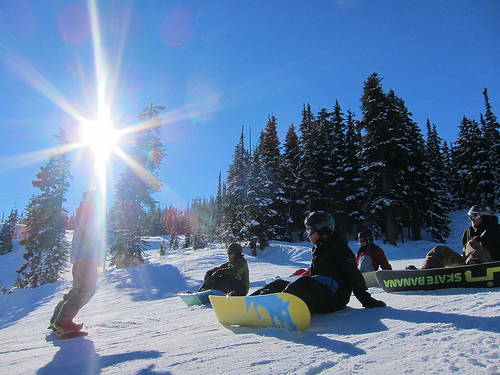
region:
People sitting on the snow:
[172, 207, 495, 332]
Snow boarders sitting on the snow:
[172, 198, 498, 333]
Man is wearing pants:
[245, 276, 347, 317]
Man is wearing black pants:
[247, 275, 350, 310]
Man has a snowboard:
[205, 288, 314, 331]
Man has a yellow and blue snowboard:
[205, 287, 314, 334]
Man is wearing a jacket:
[307, 232, 370, 302]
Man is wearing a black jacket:
[307, 236, 370, 294]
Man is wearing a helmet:
[305, 207, 335, 235]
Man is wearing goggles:
[300, 216, 337, 231]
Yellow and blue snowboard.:
[208, 293, 310, 333]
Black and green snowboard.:
[371, 261, 498, 293]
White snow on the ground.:
[3, 215, 497, 372]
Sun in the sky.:
[72, 105, 129, 165]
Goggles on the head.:
[300, 207, 335, 246]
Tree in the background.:
[112, 99, 165, 265]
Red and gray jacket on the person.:
[353, 225, 391, 277]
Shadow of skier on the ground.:
[35, 330, 173, 372]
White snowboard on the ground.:
[361, 268, 378, 290]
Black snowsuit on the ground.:
[253, 208, 381, 318]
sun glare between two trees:
[33, 61, 162, 173]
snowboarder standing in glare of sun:
[36, 107, 130, 345]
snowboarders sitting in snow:
[173, 197, 499, 343]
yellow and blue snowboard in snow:
[206, 292, 311, 334]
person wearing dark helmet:
[301, 208, 333, 252]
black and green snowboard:
[371, 258, 498, 296]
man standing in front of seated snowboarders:
[37, 185, 499, 342]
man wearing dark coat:
[297, 210, 366, 297]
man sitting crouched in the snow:
[200, 240, 254, 292]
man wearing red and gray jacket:
[353, 228, 394, 273]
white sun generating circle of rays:
[7, 7, 187, 262]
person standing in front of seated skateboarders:
[50, 171, 495, 336]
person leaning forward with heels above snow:
[45, 185, 100, 340]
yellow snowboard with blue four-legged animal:
[210, 290, 310, 331]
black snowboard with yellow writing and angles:
[375, 260, 495, 285]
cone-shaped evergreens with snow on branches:
[235, 70, 495, 256]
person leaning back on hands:
[285, 207, 380, 319]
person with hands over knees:
[197, 240, 247, 300]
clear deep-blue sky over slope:
[5, 5, 495, 222]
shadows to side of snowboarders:
[36, 305, 497, 370]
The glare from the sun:
[26, 60, 211, 230]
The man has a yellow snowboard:
[197, 271, 367, 352]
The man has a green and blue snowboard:
[159, 273, 254, 324]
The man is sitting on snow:
[209, 213, 482, 373]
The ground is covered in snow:
[155, 314, 443, 372]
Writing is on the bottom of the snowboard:
[370, 255, 497, 315]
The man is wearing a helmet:
[298, 197, 420, 245]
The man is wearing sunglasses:
[201, 248, 259, 276]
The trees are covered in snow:
[200, 117, 479, 249]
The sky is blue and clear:
[160, 13, 461, 105]